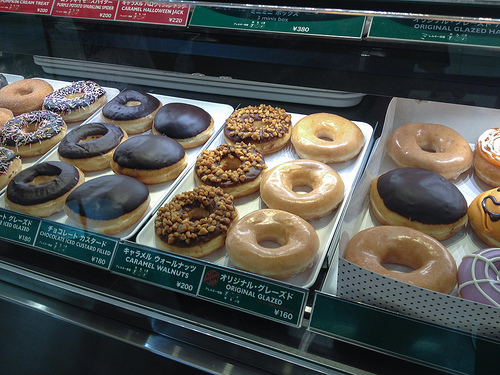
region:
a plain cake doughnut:
[3, 77, 48, 109]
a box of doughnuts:
[341, 95, 498, 341]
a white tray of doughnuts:
[132, 104, 372, 289]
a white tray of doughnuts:
[0, 88, 232, 240]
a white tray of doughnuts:
[2, 72, 115, 193]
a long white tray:
[28, 52, 363, 107]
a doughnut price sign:
[198, 261, 305, 326]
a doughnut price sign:
[108, 237, 205, 299]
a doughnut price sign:
[32, 214, 117, 274]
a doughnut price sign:
[0, 207, 38, 246]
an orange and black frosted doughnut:
[469, 187, 499, 247]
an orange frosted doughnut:
[471, 125, 498, 184]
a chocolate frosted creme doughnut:
[64, 172, 152, 237]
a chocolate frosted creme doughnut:
[110, 133, 187, 185]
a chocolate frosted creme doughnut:
[145, 100, 213, 147]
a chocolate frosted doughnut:
[101, 88, 163, 135]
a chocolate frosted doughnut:
[56, 122, 124, 168]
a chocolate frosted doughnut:
[8, 162, 82, 215]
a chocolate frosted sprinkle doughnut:
[42, 81, 106, 118]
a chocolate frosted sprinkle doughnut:
[4, 107, 66, 155]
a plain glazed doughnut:
[254, 156, 343, 216]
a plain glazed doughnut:
[291, 108, 365, 161]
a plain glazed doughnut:
[389, 116, 469, 176]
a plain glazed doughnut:
[347, 223, 452, 297]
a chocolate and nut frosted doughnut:
[156, 188, 237, 257]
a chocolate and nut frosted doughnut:
[196, 143, 262, 196]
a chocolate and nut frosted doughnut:
[221, 103, 291, 152]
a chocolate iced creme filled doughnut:
[367, 165, 469, 240]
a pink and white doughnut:
[459, 243, 499, 309]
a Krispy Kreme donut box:
[324, 95, 498, 360]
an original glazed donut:
[226, 205, 318, 277]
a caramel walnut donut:
[148, 183, 241, 254]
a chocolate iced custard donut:
[64, 176, 146, 234]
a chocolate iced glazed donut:
[61, 120, 128, 169]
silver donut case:
[0, 255, 361, 373]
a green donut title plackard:
[195, 261, 302, 329]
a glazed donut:
[259, 160, 343, 217]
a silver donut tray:
[24, 53, 363, 108]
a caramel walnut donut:
[195, 141, 263, 195]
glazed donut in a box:
[343, 221, 458, 301]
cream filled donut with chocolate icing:
[367, 166, 472, 243]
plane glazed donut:
[386, 118, 471, 179]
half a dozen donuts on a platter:
[136, 100, 368, 300]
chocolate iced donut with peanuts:
[150, 185, 235, 257]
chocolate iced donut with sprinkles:
[2, 110, 67, 152]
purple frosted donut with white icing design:
[457, 244, 499, 306]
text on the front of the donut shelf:
[197, 258, 301, 323]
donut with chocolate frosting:
[9, 160, 86, 217]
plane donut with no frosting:
[1, 78, 48, 109]